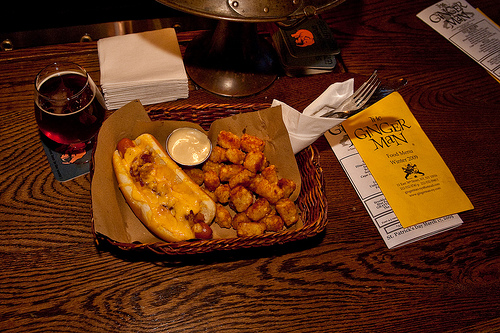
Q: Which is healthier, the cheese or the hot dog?
A: The cheese is healthier than the hot dog.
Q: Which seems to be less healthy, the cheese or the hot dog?
A: The hot dog is less healthy than the cheese.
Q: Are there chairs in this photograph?
A: No, there are no chairs.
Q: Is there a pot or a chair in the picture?
A: No, there are no chairs or pots.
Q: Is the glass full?
A: Yes, the glass is full.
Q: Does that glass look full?
A: Yes, the glass is full.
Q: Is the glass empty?
A: No, the glass is full.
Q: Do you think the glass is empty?
A: No, the glass is full.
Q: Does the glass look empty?
A: No, the glass is full.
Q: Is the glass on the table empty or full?
A: The glass is full.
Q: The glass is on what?
A: The glass is on the table.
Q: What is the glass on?
A: The glass is on the table.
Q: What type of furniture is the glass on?
A: The glass is on the table.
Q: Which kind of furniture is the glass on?
A: The glass is on the table.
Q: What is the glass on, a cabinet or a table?
A: The glass is on a table.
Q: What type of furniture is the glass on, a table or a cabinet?
A: The glass is on a table.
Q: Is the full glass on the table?
A: Yes, the glass is on the table.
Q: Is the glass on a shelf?
A: No, the glass is on the table.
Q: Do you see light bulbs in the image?
A: No, there are no light bulbs.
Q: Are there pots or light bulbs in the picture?
A: No, there are no light bulbs or pots.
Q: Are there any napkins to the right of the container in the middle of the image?
A: Yes, there is a napkin to the right of the container.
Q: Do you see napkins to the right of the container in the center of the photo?
A: Yes, there is a napkin to the right of the container.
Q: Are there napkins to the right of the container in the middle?
A: Yes, there is a napkin to the right of the container.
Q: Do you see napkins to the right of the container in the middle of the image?
A: Yes, there is a napkin to the right of the container.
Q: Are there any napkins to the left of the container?
A: No, the napkin is to the right of the container.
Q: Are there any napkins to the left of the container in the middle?
A: No, the napkin is to the right of the container.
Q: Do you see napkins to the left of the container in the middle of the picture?
A: No, the napkin is to the right of the container.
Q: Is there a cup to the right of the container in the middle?
A: No, there is a napkin to the right of the container.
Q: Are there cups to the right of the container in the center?
A: No, there is a napkin to the right of the container.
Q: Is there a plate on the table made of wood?
A: No, there is a napkin on the table.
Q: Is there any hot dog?
A: Yes, there is a hot dog.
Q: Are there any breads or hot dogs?
A: Yes, there is a hot dog.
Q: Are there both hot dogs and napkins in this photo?
A: Yes, there are both a hot dog and a napkin.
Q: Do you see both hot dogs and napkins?
A: Yes, there are both a hot dog and a napkin.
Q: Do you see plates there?
A: No, there are no plates.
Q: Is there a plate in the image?
A: No, there are no plates.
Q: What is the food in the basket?
A: The food is a hot dog.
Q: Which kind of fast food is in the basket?
A: The food is a hot dog.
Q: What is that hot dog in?
A: The hot dog is in the basket.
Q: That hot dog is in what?
A: The hot dog is in the basket.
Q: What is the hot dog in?
A: The hot dog is in the basket.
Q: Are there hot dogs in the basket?
A: Yes, there is a hot dog in the basket.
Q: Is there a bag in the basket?
A: No, there is a hot dog in the basket.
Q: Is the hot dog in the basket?
A: Yes, the hot dog is in the basket.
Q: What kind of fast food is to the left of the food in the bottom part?
A: The food is a hot dog.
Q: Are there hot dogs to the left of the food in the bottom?
A: Yes, there is a hot dog to the left of the food.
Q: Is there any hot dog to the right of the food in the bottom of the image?
A: No, the hot dog is to the left of the food.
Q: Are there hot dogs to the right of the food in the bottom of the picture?
A: No, the hot dog is to the left of the food.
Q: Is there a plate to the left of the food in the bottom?
A: No, there is a hot dog to the left of the food.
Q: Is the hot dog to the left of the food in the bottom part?
A: Yes, the hot dog is to the left of the food.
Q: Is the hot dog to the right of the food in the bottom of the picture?
A: No, the hot dog is to the left of the food.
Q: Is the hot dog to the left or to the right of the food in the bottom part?
A: The hot dog is to the left of the food.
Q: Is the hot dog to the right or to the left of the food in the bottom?
A: The hot dog is to the left of the food.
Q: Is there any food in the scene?
A: Yes, there is food.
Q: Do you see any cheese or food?
A: Yes, there is food.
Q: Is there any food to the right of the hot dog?
A: Yes, there is food to the right of the hot dog.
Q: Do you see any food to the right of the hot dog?
A: Yes, there is food to the right of the hot dog.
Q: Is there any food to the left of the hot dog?
A: No, the food is to the right of the hot dog.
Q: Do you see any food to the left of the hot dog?
A: No, the food is to the right of the hot dog.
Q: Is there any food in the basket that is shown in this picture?
A: Yes, there is food in the basket.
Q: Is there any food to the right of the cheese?
A: Yes, there is food to the right of the cheese.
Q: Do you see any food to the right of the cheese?
A: Yes, there is food to the right of the cheese.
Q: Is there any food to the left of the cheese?
A: No, the food is to the right of the cheese.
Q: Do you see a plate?
A: No, there are no plates.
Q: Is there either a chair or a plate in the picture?
A: No, there are no plates or chairs.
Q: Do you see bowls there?
A: No, there are no bowls.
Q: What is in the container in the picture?
A: The sauce is in the container.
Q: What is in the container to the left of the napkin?
A: The sauce is in the container.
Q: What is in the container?
A: The sauce is in the container.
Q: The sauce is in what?
A: The sauce is in the container.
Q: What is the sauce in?
A: The sauce is in the container.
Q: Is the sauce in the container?
A: Yes, the sauce is in the container.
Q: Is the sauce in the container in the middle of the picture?
A: Yes, the sauce is in the container.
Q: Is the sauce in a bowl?
A: No, the sauce is in the container.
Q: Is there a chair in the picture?
A: No, there are no chairs.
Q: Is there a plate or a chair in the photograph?
A: No, there are no chairs or plates.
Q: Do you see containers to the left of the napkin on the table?
A: Yes, there is a container to the left of the napkin.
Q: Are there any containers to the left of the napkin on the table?
A: Yes, there is a container to the left of the napkin.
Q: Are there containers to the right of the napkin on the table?
A: No, the container is to the left of the napkin.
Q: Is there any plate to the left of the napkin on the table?
A: No, there is a container to the left of the napkin.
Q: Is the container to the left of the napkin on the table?
A: Yes, the container is to the left of the napkin.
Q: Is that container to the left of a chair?
A: No, the container is to the left of the napkin.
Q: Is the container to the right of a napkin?
A: No, the container is to the left of a napkin.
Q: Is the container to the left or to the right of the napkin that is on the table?
A: The container is to the left of the napkin.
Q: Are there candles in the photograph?
A: No, there are no candles.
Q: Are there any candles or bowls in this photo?
A: No, there are no candles or bowls.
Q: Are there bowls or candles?
A: No, there are no candles or bowls.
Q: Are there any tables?
A: Yes, there is a table.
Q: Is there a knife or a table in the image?
A: Yes, there is a table.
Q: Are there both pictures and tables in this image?
A: No, there is a table but no pictures.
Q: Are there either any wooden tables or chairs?
A: Yes, there is a wood table.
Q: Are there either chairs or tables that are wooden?
A: Yes, the table is wooden.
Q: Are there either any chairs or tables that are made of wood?
A: Yes, the table is made of wood.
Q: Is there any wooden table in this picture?
A: Yes, there is a wood table.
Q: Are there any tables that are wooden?
A: Yes, there is a table that is wooden.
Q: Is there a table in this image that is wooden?
A: Yes, there is a table that is wooden.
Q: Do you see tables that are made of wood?
A: Yes, there is a table that is made of wood.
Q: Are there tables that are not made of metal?
A: Yes, there is a table that is made of wood.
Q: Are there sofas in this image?
A: No, there are no sofas.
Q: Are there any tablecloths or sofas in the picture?
A: No, there are no sofas or tablecloths.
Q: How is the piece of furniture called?
A: The piece of furniture is a table.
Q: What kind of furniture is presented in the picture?
A: The furniture is a table.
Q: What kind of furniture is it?
A: The piece of furniture is a table.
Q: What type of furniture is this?
A: This is a table.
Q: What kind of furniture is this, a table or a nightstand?
A: This is a table.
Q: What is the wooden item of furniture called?
A: The piece of furniture is a table.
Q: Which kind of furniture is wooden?
A: The furniture is a table.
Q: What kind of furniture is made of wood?
A: The furniture is a table.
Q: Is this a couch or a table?
A: This is a table.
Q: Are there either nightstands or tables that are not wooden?
A: No, there is a table but it is wooden.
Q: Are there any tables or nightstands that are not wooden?
A: No, there is a table but it is wooden.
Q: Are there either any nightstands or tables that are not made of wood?
A: No, there is a table but it is made of wood.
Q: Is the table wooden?
A: Yes, the table is wooden.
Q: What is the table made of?
A: The table is made of wood.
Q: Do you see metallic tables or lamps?
A: No, there is a table but it is wooden.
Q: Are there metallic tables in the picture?
A: No, there is a table but it is wooden.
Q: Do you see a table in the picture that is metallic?
A: No, there is a table but it is wooden.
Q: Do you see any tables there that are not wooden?
A: No, there is a table but it is wooden.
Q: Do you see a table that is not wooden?
A: No, there is a table but it is wooden.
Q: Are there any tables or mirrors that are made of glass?
A: No, there is a table but it is made of wood.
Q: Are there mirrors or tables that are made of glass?
A: No, there is a table but it is made of wood.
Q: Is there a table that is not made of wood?
A: No, there is a table but it is made of wood.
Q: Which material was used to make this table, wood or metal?
A: The table is made of wood.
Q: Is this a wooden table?
A: Yes, this is a wooden table.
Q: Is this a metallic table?
A: No, this is a wooden table.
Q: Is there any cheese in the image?
A: Yes, there is cheese.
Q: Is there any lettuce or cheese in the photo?
A: Yes, there is cheese.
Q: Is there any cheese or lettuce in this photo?
A: Yes, there is cheese.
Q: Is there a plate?
A: No, there are no plates.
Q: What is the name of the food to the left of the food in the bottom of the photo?
A: The food is cheese.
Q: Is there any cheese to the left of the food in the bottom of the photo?
A: Yes, there is cheese to the left of the food.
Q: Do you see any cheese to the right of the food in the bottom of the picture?
A: No, the cheese is to the left of the food.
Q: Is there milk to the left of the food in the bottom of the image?
A: No, there is cheese to the left of the food.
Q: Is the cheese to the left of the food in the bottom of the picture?
A: Yes, the cheese is to the left of the food.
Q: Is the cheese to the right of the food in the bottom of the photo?
A: No, the cheese is to the left of the food.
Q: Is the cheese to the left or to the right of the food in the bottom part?
A: The cheese is to the left of the food.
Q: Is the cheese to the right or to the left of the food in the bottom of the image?
A: The cheese is to the left of the food.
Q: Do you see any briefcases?
A: No, there are no briefcases.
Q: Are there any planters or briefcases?
A: No, there are no briefcases or planters.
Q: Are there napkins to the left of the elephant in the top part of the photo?
A: Yes, there are napkins to the left of the elephant.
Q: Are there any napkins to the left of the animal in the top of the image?
A: Yes, there are napkins to the left of the elephant.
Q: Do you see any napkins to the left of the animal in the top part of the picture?
A: Yes, there are napkins to the left of the elephant.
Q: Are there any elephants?
A: Yes, there is an elephant.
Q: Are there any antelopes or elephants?
A: Yes, there is an elephant.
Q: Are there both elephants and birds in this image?
A: No, there is an elephant but no birds.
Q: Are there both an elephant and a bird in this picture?
A: No, there is an elephant but no birds.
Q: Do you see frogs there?
A: No, there are no frogs.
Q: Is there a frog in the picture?
A: No, there are no frogs.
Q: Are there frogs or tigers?
A: No, there are no frogs or tigers.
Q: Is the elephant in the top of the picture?
A: Yes, the elephant is in the top of the image.